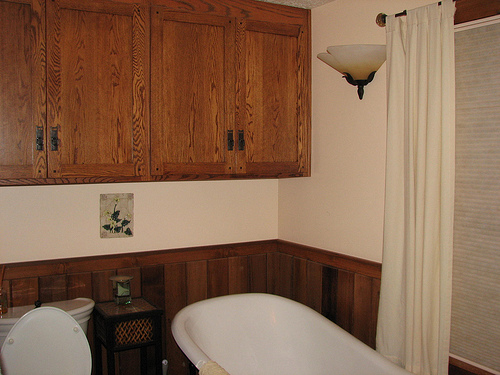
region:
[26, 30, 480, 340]
this is in a bathroom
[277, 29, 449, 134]
this is an overhead light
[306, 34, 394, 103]
the light is white and black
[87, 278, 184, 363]
this is a little table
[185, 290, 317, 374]
this is a bathtub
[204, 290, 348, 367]
the bathtub is white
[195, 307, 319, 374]
the bathtub is made of porcelin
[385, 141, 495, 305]
this is a window curtain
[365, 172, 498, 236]
the curtain is white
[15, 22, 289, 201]
these are wooden cabinets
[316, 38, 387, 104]
vintage style wall sconce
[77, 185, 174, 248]
wall art on a pink background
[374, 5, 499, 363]
window with curtains and blinds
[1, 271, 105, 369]
toilet with the seat up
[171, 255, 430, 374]
empty clawfoot bathtub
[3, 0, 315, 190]
tall oak cabinets on the wall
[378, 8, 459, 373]
white panel curtains on a window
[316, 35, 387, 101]
old style wall sconce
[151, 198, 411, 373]
bathtub in the corner of a bathroom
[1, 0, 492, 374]
outdated white and oak bathroom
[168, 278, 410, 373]
white empty bath tub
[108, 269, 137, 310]
candle on a stand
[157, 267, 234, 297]
wooden paneling in a bathroom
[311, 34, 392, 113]
light mounted on the wall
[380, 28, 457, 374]
long white curtain over a window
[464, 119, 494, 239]
white blind on a window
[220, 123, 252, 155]
black handles on a cupboard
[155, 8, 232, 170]
wood paneled cup board door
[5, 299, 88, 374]
white lid on a toilet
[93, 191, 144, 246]
artwork of a plant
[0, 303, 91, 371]
White toilet seat up in the corner.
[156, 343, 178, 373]
White toilet seat up in the corner.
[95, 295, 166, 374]
Small brown table with thin legs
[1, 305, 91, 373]
White opent toilet seat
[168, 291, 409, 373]
White bathtub next to window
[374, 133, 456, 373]
Plain white curtain in bathroom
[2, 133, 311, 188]
Old wooden cabinets with black handles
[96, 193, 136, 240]
Tile with flowers and green leaves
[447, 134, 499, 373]
White shade over bathroom window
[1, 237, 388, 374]
Wood paneling on half of bathroom wall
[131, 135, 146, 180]
Wood grain on front of cabinets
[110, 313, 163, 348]
Woven pattern on front of small table